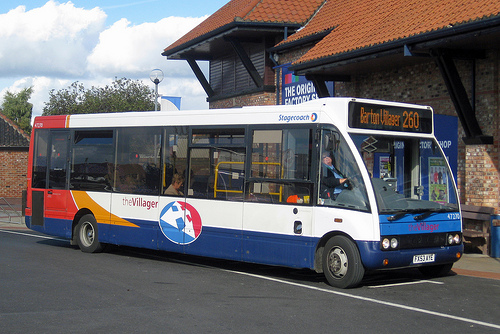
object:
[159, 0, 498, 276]
store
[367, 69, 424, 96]
part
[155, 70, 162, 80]
part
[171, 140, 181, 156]
part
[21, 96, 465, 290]
bus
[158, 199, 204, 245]
arrows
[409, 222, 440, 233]
letters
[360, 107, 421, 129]
words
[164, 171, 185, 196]
woman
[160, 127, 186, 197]
window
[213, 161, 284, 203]
handrail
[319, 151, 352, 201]
driver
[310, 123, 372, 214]
window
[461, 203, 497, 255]
bench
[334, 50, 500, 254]
wall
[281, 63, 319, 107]
sign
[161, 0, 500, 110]
building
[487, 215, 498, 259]
trashcan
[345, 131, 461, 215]
window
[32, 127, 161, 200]
windows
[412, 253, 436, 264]
license plate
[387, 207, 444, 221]
wipers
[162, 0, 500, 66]
roof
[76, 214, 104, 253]
wheel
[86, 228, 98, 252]
part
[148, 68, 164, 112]
light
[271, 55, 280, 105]
pipe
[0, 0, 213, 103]
cloud